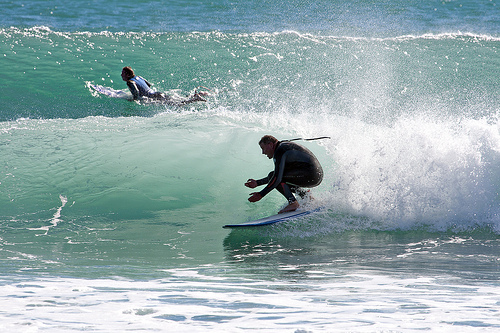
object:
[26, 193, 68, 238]
seafoam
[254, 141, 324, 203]
wet suit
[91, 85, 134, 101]
board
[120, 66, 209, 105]
man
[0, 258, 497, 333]
foam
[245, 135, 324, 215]
man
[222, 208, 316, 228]
surfboard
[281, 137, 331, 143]
rope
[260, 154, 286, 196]
arms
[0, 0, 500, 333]
water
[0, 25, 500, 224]
wave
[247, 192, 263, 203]
hands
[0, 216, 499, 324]
ripples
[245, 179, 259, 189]
hands